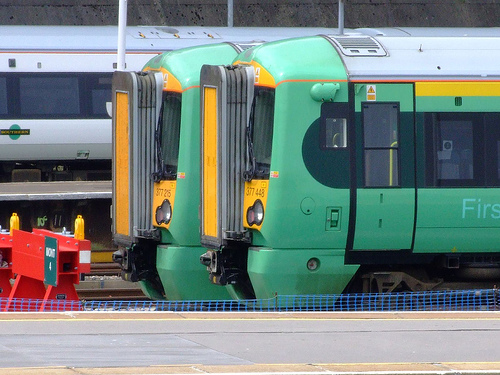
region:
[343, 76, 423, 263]
a door on a train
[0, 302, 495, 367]
a road by a train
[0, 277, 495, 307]
blue netting next to a road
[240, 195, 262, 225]
a headlight on a train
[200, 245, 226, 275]
a coupler on a train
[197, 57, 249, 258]
a connecting doorway on a train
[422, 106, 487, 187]
a window on a train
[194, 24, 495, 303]
an aqua colored train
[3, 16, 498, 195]
a white train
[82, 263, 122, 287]
gravel along the train tracks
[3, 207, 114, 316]
red device to stop a train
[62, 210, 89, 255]
yellow warning lights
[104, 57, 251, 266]
accordian doors on a train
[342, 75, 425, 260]
door on a green train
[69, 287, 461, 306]
blue snow fencing along the tracks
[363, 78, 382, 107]
white and yellow warning sticker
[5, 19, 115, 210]
white passenger train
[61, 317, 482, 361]
empty platform next to the train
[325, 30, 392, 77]
vent on the ceiling of a train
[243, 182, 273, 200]
black numbers on a yellow background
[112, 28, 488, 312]
the trains are visible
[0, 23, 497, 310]
three trains on railroad road tracks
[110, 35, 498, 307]
two green and yellow trains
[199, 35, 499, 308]
train 377448 on the railroad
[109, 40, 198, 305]
the back of a train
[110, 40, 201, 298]
back of green and yellow between two trains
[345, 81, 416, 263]
side door on a green and yellow train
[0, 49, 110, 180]
transit train for passengers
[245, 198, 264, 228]
lights on the back of train car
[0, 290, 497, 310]
blue net on the side of train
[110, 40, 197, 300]
back of yellow and green train beside another green and yellow train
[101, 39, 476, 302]
Two green and yellow trains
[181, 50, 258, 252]
Yellow and grey door on front of train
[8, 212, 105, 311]
Red stop at end of tracks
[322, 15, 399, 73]
Vent on top of train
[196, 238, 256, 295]
Coupling on front of train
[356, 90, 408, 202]
Window on train door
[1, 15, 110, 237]
White and grey train in background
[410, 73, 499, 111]
Yellow stripe on side of train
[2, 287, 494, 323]
Blue construction fence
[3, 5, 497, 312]
Three trains in picture